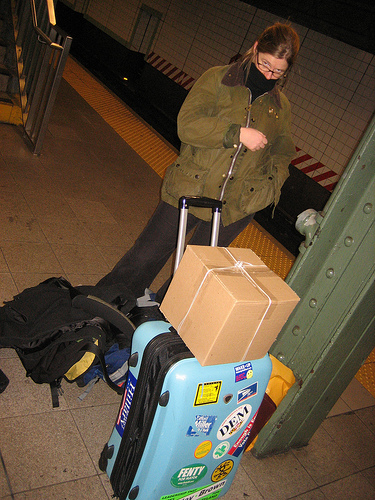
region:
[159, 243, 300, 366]
the cardboard box on the luggage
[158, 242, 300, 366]
the sealed up cardboard box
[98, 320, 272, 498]
the light blue hard case luggage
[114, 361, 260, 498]
the stickers all over the luggage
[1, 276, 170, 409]
the bags on the ground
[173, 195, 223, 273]
the handle for the luggage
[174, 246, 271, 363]
the string wrapped around the box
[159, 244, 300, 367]
the tape sealing the box shut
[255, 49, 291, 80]
the glasses on the woman's face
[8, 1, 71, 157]
the handrail for the stairs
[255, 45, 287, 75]
woman wearing glasses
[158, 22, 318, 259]
woman wearing a green jacket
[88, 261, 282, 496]
big blue luggage bag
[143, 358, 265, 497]
stickers on blue luggage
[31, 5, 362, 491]
woman waiting at train station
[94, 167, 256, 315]
woman wearing black pants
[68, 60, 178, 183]
yellow bumpy clear off area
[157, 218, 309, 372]
box tied with a string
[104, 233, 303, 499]
box sitting on luggage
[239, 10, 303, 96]
woman looking at the camera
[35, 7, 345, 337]
a woman standing on a subway platform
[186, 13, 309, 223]
a woman wearing a green jacket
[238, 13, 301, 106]
a woman with her face in her collar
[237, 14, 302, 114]
a woman wearing a black turtleneck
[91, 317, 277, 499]
a blue and black suitcase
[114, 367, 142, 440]
a Hillary Clinton for President sticker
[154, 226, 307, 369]
a brown cardboard box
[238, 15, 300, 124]
a woman with brown hair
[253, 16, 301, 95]
a woman wearing glasses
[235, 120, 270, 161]
the hand of a woman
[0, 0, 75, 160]
stairwell with steel railing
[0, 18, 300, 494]
woman waiting with her luggage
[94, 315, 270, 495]
woman's blue and black luggage with handle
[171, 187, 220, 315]
handle attached to woman's luggage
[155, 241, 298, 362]
brown box sitting on top of woman's luggage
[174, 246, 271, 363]
white string binding brown box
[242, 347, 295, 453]
manila envelope sitting on floor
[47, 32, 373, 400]
caution strip with raised bumps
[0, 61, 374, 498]
dingy brown floor tile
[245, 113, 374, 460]
green steel support beam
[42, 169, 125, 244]
a dark grey sidewalk.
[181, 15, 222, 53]
a white tiled wall.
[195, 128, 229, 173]
a woman is wearing a green jacket.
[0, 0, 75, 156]
a staircase of steps.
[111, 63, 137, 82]
a small yellow light.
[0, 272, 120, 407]
a black back pack is on the ground.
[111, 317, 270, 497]
a light blue luggage with stickers.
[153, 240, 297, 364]
a big brown card board box.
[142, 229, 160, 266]
a woman is wearing black jeans.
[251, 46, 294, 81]
a woman is wearing glasses.